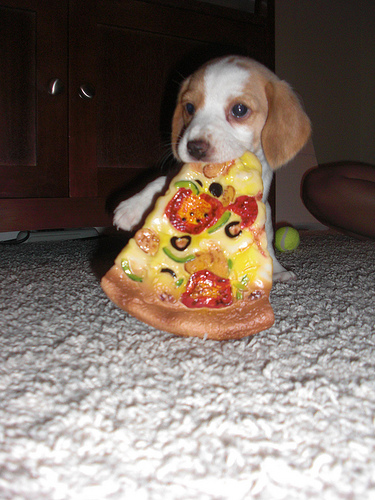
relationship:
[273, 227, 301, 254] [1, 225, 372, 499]
ball on carpet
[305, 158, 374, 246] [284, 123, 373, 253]
folded leg on person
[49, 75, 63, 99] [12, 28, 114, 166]
knob on door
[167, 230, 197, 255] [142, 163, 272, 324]
olive on pizza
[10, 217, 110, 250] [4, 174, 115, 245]
electricity under cabinet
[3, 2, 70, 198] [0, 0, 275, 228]
door on wooden cabinet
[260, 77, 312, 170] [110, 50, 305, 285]
ear on dog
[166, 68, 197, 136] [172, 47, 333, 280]
ear on dog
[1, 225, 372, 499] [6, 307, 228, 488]
carpet on ground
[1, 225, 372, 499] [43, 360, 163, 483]
carpet on ground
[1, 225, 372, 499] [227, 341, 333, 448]
carpet on ground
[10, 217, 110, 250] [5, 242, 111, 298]
electricity on ground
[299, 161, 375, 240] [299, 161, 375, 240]
folded leg sitting with folded leg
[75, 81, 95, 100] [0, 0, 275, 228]
knob on wooden cabinet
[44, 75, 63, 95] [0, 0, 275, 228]
knob on wooden cabinet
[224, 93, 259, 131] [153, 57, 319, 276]
eye of puppy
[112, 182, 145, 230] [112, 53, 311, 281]
paw of puppy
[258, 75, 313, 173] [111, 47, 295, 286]
ear of puppy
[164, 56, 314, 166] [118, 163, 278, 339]
puppy eating pizza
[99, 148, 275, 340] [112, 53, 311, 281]
pizza in mouth of puppy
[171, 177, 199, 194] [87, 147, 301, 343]
green pepper on pizza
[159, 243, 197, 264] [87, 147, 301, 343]
green pepper on pizza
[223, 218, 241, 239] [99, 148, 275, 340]
olive slice on pizza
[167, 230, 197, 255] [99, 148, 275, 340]
olive on pizza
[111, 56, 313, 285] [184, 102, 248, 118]
puppy with eyes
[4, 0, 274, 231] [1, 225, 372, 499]
wooden cabinet on carpet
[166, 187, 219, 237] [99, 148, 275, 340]
tomato slice on pizza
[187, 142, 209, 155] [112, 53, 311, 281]
nose of a puppy